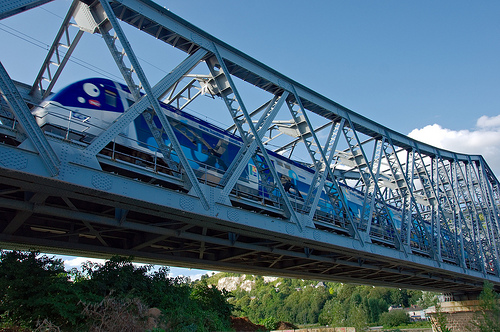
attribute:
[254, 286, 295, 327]
tree — green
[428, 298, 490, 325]
wall — brick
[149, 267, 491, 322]
bluff — steep, rocky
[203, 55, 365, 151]
bridge beam — metal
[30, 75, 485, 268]
train — bringing people, blue, white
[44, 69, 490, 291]
train — modern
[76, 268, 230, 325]
leaves — green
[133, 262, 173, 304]
bush — green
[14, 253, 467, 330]
leaves — in back, green